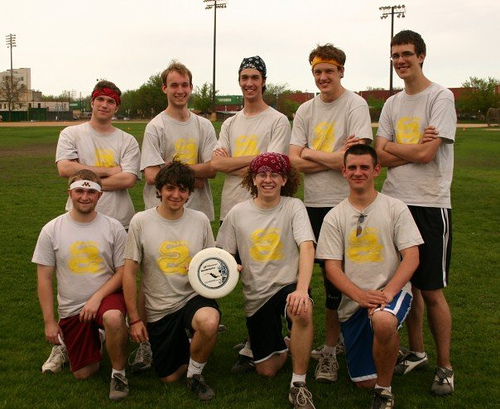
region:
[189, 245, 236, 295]
A white frisbee above the grass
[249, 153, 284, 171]
This man is wearing a red bandana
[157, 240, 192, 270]
A snake logo on the shirt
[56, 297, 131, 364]
This man is wearing red shorts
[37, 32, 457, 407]
A group of men posing for a camera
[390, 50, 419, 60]
The man is wearing glasses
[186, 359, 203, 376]
The man is wearing white socks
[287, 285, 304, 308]
The left hand of the man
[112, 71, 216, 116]
Trees behind the group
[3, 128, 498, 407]
A grassy field beneath the men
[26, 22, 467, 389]
a group of young men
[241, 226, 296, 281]
yellow writing on a shirt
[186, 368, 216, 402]
gray and black tennis shoe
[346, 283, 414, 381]
a pair of blue and white shorts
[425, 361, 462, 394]
a tan and white tennis shoe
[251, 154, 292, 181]
a red scarf on a head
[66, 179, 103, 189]
a white and red sweat band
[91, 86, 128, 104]
a red sweat band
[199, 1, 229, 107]
a metal light pole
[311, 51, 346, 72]
a yellow sweat band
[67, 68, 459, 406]
people posing to take photographs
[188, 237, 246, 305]
white color people holding frisbee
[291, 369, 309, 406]
a person wearing shoe and socks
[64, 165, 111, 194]
a person wearing hat on his head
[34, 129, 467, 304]
everyone are wearing whote color t-shirt with shorts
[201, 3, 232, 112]
electric post behind the people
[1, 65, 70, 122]
building near the lawn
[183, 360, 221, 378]
a person wearing white color socks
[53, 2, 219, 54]
sky with clouds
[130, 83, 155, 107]
trees and plants near the ground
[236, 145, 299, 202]
red bandana on curly hair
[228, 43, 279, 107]
black bandana on thin boy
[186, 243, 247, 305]
white frisbee with black markings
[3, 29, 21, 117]
tall light pole in background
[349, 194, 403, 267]
sunglasses hanging on shirt collar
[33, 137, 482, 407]
four boys kneeling in the grass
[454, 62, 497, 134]
short tree in background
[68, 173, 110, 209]
white sweatband with red letter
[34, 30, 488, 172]
four boys with arms crossed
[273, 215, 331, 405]
hand on knee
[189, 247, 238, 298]
A round white frisbee.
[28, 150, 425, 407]
A row of guys getting down on one knee.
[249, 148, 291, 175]
A red bandana.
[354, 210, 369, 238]
A pair of sunglasses.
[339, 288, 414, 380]
Blue sports shorts with white stripes down the sides.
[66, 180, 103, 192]
A white headband with a "M" on it.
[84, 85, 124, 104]
A red headband.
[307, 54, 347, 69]
A yellow bandana headband.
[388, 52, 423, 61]
A pair of glasses.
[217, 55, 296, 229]
A guy wearing a green bandana on his head